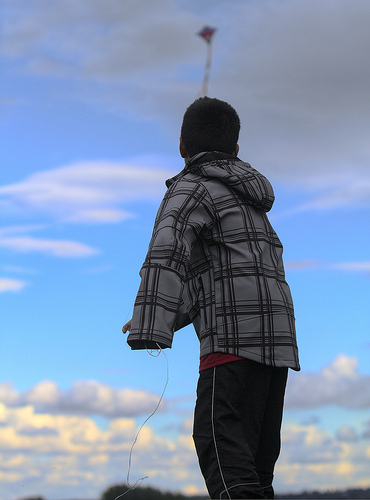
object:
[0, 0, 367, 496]
picture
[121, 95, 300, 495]
boy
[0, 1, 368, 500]
sky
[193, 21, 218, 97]
kite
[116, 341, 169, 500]
string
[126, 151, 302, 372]
jacket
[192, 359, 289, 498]
pants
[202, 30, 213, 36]
red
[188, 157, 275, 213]
hood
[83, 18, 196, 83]
top clouds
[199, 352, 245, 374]
shirt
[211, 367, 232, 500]
lines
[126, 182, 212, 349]
sleeve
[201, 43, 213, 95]
tail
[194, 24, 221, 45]
diamond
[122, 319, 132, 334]
finger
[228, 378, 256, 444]
black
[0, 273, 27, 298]
clouds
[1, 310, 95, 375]
blue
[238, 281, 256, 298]
grey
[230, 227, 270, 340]
pattern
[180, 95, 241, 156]
hair